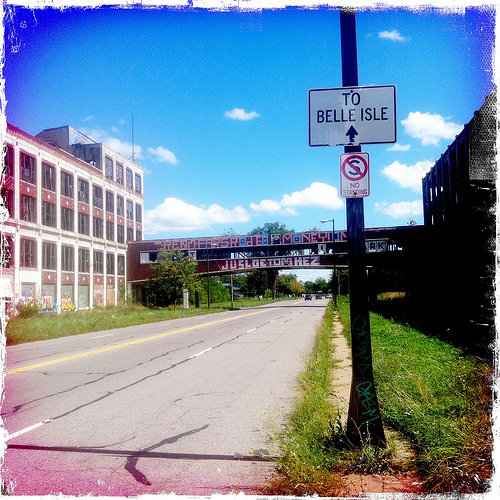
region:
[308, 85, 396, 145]
this is a sign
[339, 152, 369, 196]
this is a sign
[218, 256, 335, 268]
this is a sign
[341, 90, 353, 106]
this is a letter on a sign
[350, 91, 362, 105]
this is a letter on a sign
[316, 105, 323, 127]
this is a letter on a sign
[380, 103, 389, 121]
this is a letter on a sign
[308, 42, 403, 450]
this is a post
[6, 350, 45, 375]
this is a line on the road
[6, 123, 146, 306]
this is a building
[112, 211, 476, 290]
this is a bridge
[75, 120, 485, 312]
this bridge overpass connects two buildings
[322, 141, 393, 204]
this sign is white, red, and black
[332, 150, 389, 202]
the sign says "NO STAYING"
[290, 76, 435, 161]
a white sign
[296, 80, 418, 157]
the text on the sign is black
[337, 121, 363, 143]
this is an arrow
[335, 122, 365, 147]
a black arrow on a sign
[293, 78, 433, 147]
the sign says "TO BELLE ISLE"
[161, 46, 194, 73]
this is the sky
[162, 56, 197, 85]
the sky is blue in color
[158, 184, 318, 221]
the sky has clouds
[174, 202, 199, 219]
the clouds are white in color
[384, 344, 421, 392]
the grass is green in color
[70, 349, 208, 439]
this is the road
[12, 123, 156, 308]
this is a building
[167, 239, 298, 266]
this is a bridge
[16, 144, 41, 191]
This is a window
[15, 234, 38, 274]
This is a window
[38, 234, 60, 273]
This is a window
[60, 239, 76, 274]
This is a window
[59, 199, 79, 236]
This is a window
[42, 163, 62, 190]
This is a window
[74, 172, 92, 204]
This is a window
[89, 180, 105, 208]
This is a window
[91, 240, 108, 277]
This is a window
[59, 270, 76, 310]
This is a window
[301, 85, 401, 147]
white and black rectangular sign on pole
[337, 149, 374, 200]
red white and black sign on pole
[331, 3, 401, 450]
black metal pole next to street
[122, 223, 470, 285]
red covered walkway between buildings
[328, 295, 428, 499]
thin light brown dirt path next to street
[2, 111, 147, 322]
large building next to street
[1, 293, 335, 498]
gray paved concrete street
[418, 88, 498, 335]
old unused building near walkway and building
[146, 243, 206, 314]
green tree next to building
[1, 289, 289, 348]
long strip of grass along street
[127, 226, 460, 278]
bridge over the street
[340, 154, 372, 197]
red and white sign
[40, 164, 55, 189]
window on the building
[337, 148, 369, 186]
red circle in sign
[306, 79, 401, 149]
black and white sign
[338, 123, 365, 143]
black arrow on sign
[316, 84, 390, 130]
black letters on sign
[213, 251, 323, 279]
white letters on bridge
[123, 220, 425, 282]
brown bridge with grafitti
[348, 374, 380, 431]
bright green letters on pole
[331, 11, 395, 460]
brown metal sign post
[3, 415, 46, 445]
white line on street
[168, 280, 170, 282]
A green leaf on a plant